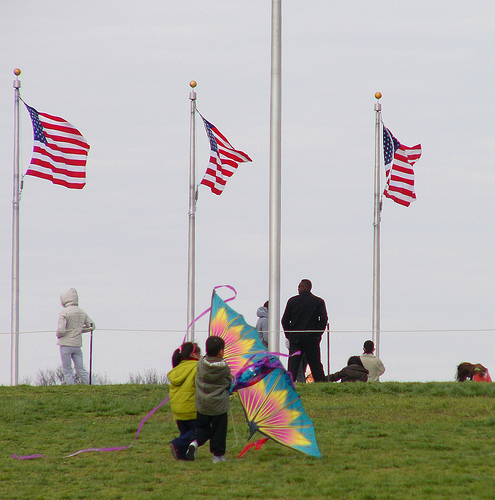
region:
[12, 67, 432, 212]
three american flags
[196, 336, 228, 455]
boy in gray jacket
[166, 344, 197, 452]
girl in yellow jacket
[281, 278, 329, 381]
man in black jacket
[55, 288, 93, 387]
child in white jacket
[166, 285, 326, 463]
children holding kites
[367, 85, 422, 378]
flag flying in wind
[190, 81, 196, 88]
ball on top of flag pole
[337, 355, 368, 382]
woman in brown jacket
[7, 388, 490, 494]
grass on the hill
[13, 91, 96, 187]
united stated flag in the wind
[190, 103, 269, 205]
united stated flag in the wind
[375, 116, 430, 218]
united stated flag in the wind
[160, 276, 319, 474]
children carrying a kite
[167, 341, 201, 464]
little girl wearing a yellow jacket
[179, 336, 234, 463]
little boy wearing a grey jacket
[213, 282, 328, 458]
big colorful kite with tail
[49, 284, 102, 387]
person wearing a white outfit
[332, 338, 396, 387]
two people sitting on grass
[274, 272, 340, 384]
man wearing a black outfit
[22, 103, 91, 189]
American flag on left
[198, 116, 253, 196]
American flag in middle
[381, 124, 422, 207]
American flag on right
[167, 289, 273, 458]
little girl with kite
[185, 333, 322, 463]
little boy with kite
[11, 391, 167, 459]
kite's long purple tail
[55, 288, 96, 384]
person in white hooded jacket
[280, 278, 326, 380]
person in black jacket and pants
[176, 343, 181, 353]
little girl has pink ribbon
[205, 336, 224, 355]
little boy has black hair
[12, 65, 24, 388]
tall metal flagpole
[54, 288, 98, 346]
dingy white hooded coat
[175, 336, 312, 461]
two children carrying a kite together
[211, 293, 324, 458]
a very bright multicolored kite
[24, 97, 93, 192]
flag of the United States of America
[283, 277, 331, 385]
man standing akimbo in black suit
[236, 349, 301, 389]
purple ribbons on a kite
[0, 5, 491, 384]
grey featureless sky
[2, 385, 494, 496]
a green grassy incline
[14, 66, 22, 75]
shiny brass ball flagpole topper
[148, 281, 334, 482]
small children with kites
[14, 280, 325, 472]
kites with purple tails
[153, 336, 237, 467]
children wearing winter jackets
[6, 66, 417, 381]
metal flag poles in row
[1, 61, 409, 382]
American flags on poles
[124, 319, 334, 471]
children walking up hill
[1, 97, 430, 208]
American flags flapping in breeze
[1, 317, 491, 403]
metal fence on top of hill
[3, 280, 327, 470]
multi colors kites with tails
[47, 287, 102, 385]
person wearing hooded white coat